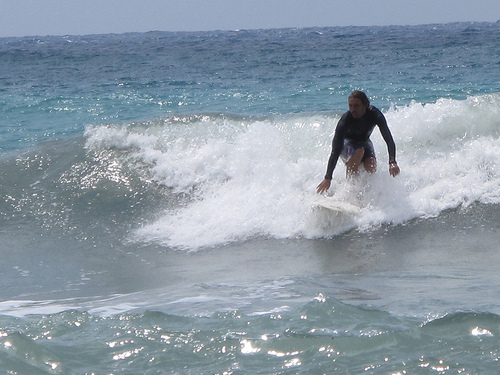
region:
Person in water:
[273, 95, 385, 185]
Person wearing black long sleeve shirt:
[306, 123, 383, 173]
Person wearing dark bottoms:
[321, 117, 398, 174]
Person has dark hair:
[331, 50, 388, 157]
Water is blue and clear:
[78, 41, 255, 101]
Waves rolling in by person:
[149, 135, 423, 244]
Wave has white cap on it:
[155, 160, 375, 236]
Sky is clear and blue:
[58, 10, 167, 26]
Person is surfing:
[277, 73, 463, 319]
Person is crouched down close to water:
[238, 50, 415, 325]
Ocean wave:
[10, 56, 237, 239]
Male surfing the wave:
[296, 83, 410, 201]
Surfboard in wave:
[310, 196, 368, 225]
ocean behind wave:
[65, 12, 334, 92]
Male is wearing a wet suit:
[333, 113, 398, 165]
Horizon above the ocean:
[41, 1, 283, 53]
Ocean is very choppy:
[115, 35, 225, 88]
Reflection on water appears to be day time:
[133, 292, 300, 364]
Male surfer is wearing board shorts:
[333, 132, 380, 164]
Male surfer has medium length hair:
[341, 89, 372, 114]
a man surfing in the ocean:
[291, 99, 443, 251]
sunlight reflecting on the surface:
[231, 320, 298, 373]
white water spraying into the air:
[229, 131, 329, 183]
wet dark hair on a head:
[352, 89, 369, 107]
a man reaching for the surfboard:
[310, 83, 399, 196]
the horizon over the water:
[114, 14, 378, 29]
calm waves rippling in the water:
[198, 42, 283, 68]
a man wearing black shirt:
[329, 81, 413, 210]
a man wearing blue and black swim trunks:
[309, 86, 426, 213]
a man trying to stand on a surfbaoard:
[321, 78, 448, 260]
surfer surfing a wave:
[314, 85, 413, 202]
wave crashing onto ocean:
[75, 134, 313, 257]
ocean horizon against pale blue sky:
[1, 2, 488, 19]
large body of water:
[1, 142, 496, 347]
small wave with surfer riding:
[78, 77, 498, 229]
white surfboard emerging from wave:
[298, 187, 439, 230]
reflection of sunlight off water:
[22, 91, 328, 128]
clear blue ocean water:
[4, 77, 261, 115]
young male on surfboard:
[321, 73, 417, 203]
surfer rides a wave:
[1, 0, 495, 374]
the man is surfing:
[278, 100, 408, 175]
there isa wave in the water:
[177, 116, 300, 231]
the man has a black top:
[298, 83, 427, 185]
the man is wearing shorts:
[329, 136, 401, 177]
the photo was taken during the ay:
[3, 58, 498, 365]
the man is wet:
[316, 85, 404, 195]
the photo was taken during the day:
[5, 55, 494, 365]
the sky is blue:
[20, 7, 468, 20]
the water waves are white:
[224, 165, 294, 210]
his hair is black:
[346, 89, 384, 105]